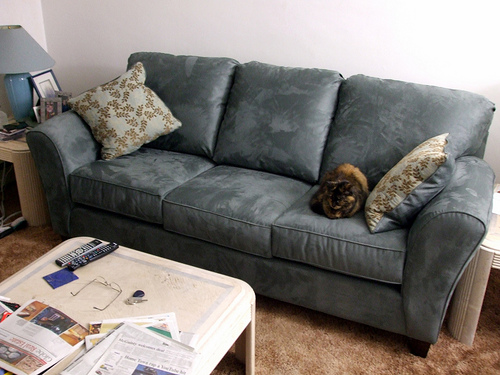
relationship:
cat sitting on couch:
[306, 160, 373, 218] [28, 48, 496, 355]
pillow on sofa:
[64, 62, 180, 160] [23, 51, 495, 357]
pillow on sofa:
[360, 126, 455, 235] [23, 51, 495, 357]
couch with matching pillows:
[28, 48, 496, 355] [67, 60, 187, 162]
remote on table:
[52, 239, 130, 281] [20, 216, 234, 372]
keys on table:
[127, 264, 143, 320] [2, 235, 281, 372]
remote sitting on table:
[56, 240, 120, 272] [4, 247, 229, 372]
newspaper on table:
[0, 299, 196, 374] [140, 258, 262, 370]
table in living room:
[2, 235, 256, 374] [26, 14, 491, 372]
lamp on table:
[0, 25, 56, 130] [0, 78, 90, 229]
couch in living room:
[28, 48, 496, 355] [19, 20, 483, 349]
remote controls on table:
[45, 234, 125, 275] [2, 235, 256, 374]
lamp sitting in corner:
[0, 22, 55, 120] [10, 11, 146, 214]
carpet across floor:
[1, 222, 497, 373] [16, 221, 483, 372]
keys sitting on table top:
[127, 290, 148, 306] [0, 220, 257, 374]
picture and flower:
[28, 68, 63, 99] [52, 89, 72, 104]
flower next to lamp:
[52, 89, 72, 104] [0, 13, 60, 124]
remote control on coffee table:
[57, 234, 99, 260] [1, 233, 256, 370]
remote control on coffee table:
[70, 244, 117, 265] [1, 233, 256, 370]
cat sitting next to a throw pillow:
[306, 160, 373, 218] [365, 125, 458, 237]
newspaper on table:
[0, 314, 196, 374] [2, 235, 256, 374]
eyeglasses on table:
[67, 272, 122, 313] [2, 235, 256, 374]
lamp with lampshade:
[2, 73, 38, 123] [1, 24, 55, 73]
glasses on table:
[71, 268, 131, 316] [1, 222, 295, 372]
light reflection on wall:
[396, 1, 498, 93] [0, 1, 499, 183]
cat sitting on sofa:
[306, 160, 373, 218] [23, 51, 495, 357]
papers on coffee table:
[2, 299, 197, 373] [1, 233, 256, 370]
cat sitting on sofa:
[310, 162, 370, 219] [23, 51, 495, 357]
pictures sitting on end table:
[29, 68, 69, 124] [2, 104, 58, 230]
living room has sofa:
[0, 1, 498, 369] [23, 51, 495, 357]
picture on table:
[40, 96, 61, 120] [9, 129, 61, 255]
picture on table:
[28, 68, 61, 99] [9, 129, 61, 255]